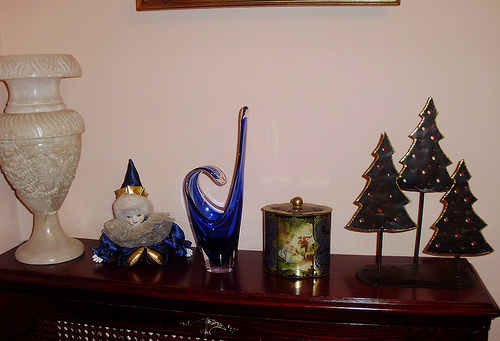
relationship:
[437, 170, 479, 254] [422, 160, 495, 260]
ornaments on tree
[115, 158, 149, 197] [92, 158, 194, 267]
hat on doll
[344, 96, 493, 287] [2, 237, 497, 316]
tree decoration on table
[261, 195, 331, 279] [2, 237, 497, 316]
container on table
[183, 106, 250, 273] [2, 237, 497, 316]
sculpture on table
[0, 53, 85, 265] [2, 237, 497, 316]
vase on table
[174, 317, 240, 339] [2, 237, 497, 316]
handle on table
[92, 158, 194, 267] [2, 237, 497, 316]
doll on table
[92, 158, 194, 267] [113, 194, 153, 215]
doll has hair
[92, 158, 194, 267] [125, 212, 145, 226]
doll has face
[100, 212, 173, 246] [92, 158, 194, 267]
collar on doll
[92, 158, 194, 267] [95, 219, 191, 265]
doll wearing outfit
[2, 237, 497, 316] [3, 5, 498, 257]
table near wall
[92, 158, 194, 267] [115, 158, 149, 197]
doll wearing hat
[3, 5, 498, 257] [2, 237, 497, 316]
wall behind table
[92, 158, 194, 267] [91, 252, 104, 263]
doll has hand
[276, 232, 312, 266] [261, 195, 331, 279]
people painted on container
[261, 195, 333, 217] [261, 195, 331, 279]
lid on container